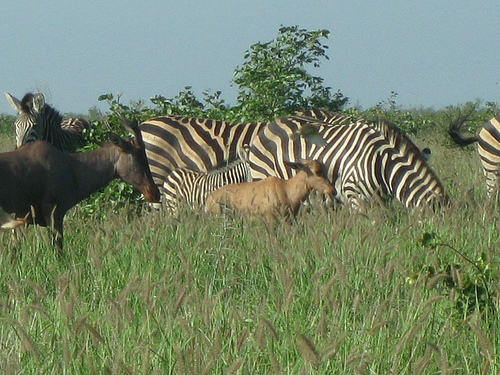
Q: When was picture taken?
A: In daytime.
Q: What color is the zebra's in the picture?
A: Black and white.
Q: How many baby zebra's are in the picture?
A: One.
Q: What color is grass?
A: Green.